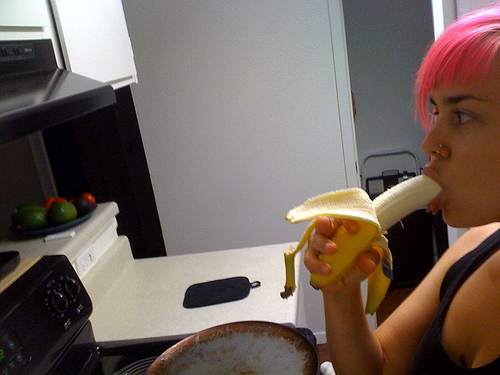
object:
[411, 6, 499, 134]
hair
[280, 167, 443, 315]
banana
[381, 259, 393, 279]
sticker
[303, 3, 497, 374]
girl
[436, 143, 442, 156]
ring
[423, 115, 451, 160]
nose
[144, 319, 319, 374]
plate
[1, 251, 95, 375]
oven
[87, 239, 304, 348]
counter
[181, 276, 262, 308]
potholder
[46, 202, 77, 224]
lime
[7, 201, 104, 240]
dish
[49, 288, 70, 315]
knob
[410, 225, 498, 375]
shirt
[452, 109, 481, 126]
eye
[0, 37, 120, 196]
hood